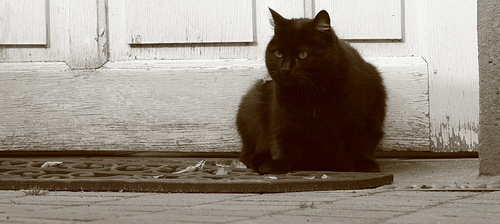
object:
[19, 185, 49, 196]
grass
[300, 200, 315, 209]
grass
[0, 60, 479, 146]
wood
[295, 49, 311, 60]
eye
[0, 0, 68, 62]
panels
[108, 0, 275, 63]
panels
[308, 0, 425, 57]
panels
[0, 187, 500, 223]
ground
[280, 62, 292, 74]
nose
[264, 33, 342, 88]
cat's face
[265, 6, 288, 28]
ear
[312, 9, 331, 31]
ear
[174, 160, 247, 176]
paper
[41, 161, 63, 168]
paper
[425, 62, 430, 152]
line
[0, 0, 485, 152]
door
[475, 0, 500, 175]
wall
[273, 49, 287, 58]
eyes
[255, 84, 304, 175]
legs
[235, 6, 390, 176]
black cat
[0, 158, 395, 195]
door mat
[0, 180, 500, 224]
bricks